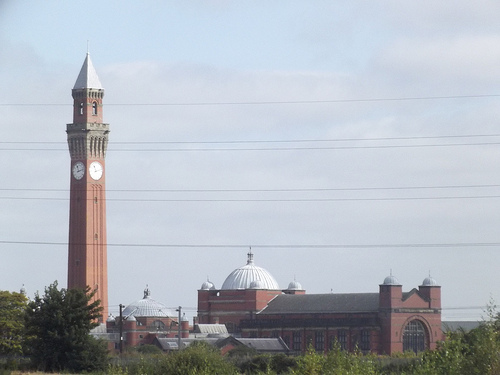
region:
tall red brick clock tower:
[58, 42, 123, 337]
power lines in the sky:
[121, 92, 498, 247]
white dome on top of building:
[225, 240, 273, 288]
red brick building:
[289, 292, 441, 354]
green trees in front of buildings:
[1, 283, 177, 373]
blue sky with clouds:
[106, 28, 460, 167]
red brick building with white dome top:
[124, 278, 200, 345]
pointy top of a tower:
[66, 37, 115, 157]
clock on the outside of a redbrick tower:
[70, 144, 112, 196]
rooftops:
[144, 320, 301, 357]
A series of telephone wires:
[201, 82, 476, 236]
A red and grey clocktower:
[55, 35, 125, 325]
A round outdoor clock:
[86, 154, 114, 188]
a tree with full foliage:
[23, 278, 120, 373]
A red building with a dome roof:
[193, 241, 312, 325]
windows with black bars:
[287, 326, 380, 359]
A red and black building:
[191, 275, 457, 360]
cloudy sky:
[133, 39, 487, 89]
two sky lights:
[160, 328, 205, 357]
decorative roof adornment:
[239, 240, 261, 270]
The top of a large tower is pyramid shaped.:
[68, 46, 115, 95]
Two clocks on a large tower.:
[62, 160, 112, 182]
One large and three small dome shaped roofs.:
[193, 246, 307, 294]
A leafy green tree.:
[18, 283, 113, 364]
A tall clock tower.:
[56, 44, 121, 333]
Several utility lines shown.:
[116, 86, 493, 207]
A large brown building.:
[180, 238, 461, 351]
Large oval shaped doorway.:
[400, 313, 438, 365]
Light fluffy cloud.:
[126, 45, 376, 87]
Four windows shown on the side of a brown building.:
[286, 329, 378, 358]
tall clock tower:
[63, 40, 110, 339]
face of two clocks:
[70, 158, 103, 183]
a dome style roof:
[221, 245, 280, 290]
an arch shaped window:
[397, 315, 436, 357]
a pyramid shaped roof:
[69, 45, 107, 92]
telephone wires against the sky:
[297, 92, 419, 222]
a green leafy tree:
[30, 281, 105, 371]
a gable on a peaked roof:
[206, 335, 251, 355]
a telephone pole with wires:
[167, 300, 189, 360]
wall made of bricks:
[74, 202, 97, 267]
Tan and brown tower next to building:
[59, 40, 111, 339]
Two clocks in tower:
[65, 157, 105, 185]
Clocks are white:
[65, 155, 118, 185]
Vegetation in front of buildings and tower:
[11, 292, 497, 372]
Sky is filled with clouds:
[0, 0, 499, 299]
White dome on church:
[219, 247, 279, 293]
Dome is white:
[215, 241, 292, 306]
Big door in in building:
[399, 317, 439, 370]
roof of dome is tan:
[68, 35, 113, 95]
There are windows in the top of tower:
[69, 98, 105, 120]